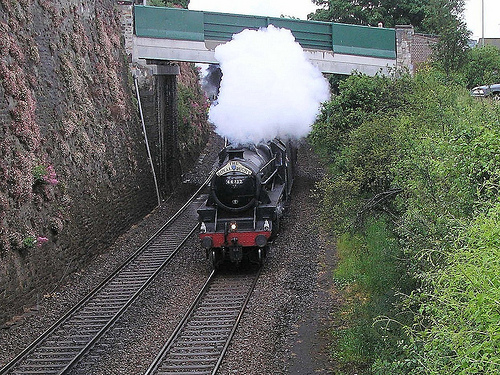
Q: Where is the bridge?
A: Above train.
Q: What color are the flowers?
A: Pink.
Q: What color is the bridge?
A: Green.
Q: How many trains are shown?
A: One.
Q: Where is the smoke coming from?
A: The train.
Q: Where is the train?
A: The tracks.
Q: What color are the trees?
A: Green.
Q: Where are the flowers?
A: The hillside.